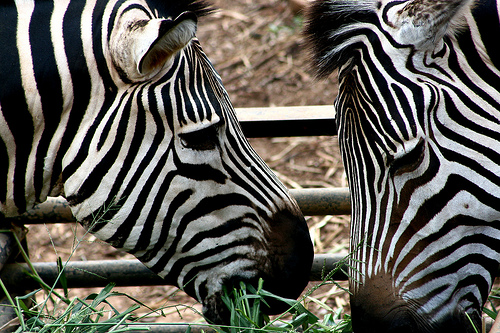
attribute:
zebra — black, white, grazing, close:
[1, 3, 314, 332]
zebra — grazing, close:
[312, 0, 498, 333]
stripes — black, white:
[8, 51, 123, 151]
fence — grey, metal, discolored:
[10, 97, 376, 307]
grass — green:
[18, 286, 345, 332]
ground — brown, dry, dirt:
[21, 1, 347, 315]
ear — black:
[119, 10, 196, 79]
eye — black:
[186, 129, 221, 148]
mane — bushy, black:
[308, 6, 371, 59]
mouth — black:
[204, 271, 295, 322]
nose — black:
[277, 220, 315, 291]